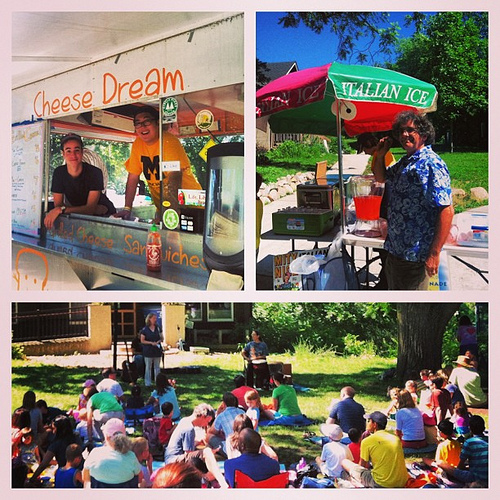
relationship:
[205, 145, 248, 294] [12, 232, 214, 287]
napkin dispenser on counter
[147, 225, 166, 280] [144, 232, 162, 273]
bottle of hot sauce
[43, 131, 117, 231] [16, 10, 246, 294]
man working truck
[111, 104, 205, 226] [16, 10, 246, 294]
man working truck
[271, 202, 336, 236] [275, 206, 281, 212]
cooler with bottle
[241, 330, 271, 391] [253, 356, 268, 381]
woman playing drum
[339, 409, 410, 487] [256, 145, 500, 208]
man on grass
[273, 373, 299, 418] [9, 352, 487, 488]
woman on grass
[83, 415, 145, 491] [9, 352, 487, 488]
man on grass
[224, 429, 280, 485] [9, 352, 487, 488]
man on grass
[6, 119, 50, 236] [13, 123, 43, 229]
board for menu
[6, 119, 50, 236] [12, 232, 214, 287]
board on counter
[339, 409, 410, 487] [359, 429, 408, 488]
man in shirt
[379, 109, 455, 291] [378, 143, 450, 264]
man wearing shirt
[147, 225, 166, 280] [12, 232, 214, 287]
bottle on counter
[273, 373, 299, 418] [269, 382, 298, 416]
woman wearing shirt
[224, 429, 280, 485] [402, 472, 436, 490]
man on pillow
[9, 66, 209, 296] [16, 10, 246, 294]
writing on truck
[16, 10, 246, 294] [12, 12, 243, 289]
truck has side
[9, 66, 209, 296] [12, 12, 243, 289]
writing on side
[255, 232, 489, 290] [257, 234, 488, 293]
walkway on walkway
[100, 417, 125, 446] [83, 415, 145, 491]
hat on man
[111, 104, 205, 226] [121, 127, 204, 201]
man wearing shirt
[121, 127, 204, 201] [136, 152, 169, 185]
shirt with word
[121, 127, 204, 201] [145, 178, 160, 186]
shirt with word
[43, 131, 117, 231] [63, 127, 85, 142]
man wearing hat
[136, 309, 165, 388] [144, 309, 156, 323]
man wearing hat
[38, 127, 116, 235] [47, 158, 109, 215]
man wearing shirt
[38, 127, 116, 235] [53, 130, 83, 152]
man wearing hat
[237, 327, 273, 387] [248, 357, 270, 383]
woman playing a drum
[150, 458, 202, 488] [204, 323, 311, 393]
people on speaker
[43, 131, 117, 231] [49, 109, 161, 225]
man looking out of window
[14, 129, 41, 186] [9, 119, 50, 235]
words on board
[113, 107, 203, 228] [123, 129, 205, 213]
man wearing shirt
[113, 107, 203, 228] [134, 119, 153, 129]
man wearing glasses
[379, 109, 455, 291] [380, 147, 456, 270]
man wearing shirt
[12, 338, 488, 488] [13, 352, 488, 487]
people sitting on grass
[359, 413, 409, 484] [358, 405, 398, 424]
man wearing a hat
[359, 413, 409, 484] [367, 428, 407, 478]
man wearing a shirt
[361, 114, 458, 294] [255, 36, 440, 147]
man under umbrella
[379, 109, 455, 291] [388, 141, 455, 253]
man wearing shirt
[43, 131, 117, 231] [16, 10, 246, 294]
man in truck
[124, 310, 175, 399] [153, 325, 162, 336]
woman speaking into microphone